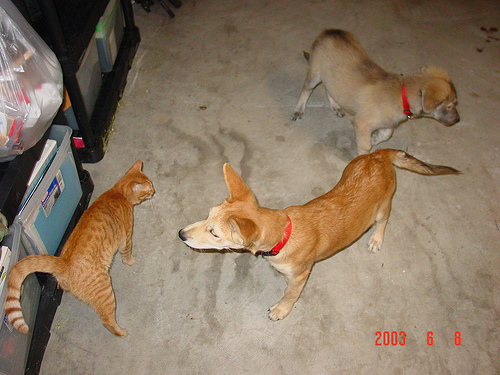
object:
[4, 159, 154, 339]
cat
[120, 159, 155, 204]
head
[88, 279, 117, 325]
leg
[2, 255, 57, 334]
tail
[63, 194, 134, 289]
body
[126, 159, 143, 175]
ear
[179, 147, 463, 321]
dog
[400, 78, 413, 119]
collar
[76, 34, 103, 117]
container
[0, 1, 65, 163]
bag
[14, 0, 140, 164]
bookshelf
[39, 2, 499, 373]
floor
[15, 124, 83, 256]
tray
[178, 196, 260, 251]
head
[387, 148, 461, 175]
tail